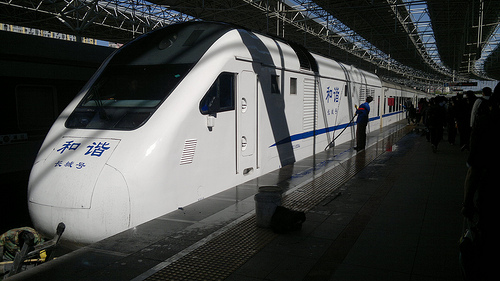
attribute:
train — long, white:
[25, 19, 455, 249]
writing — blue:
[55, 137, 112, 159]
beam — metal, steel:
[149, 27, 374, 180]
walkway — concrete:
[28, 106, 498, 276]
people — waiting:
[390, 78, 499, 279]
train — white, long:
[59, 51, 255, 178]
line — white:
[131, 117, 417, 280]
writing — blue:
[53, 139, 111, 169]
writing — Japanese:
[50, 138, 110, 175]